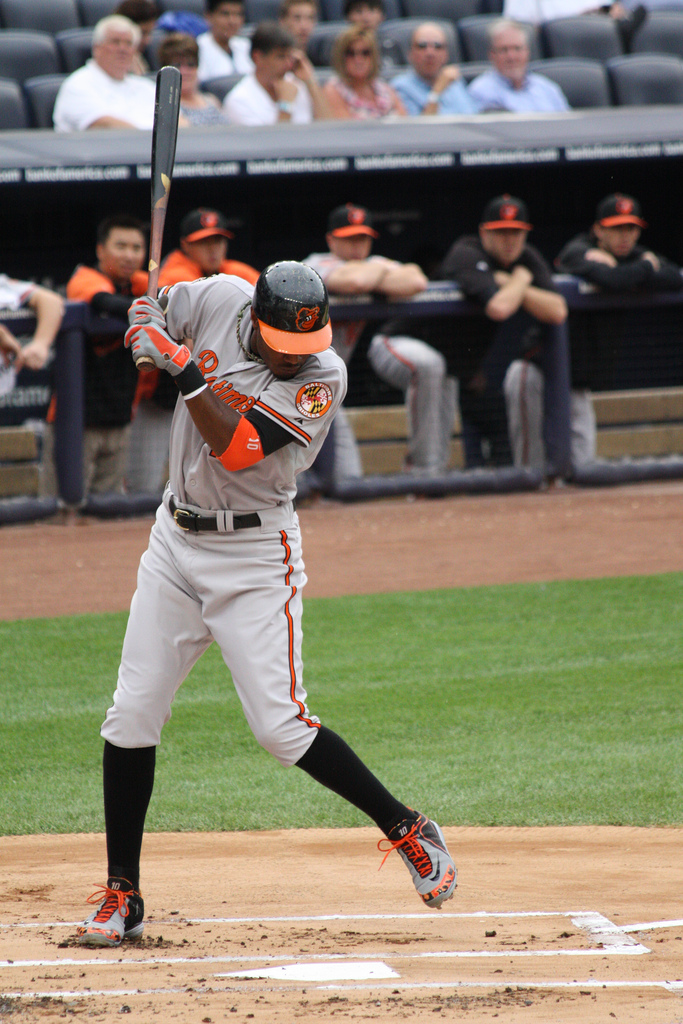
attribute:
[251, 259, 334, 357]
helmet — black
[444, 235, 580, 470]
uniform — black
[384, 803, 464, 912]
cleat — gray, black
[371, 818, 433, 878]
laces — orange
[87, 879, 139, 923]
laces — orange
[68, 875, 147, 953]
cleat — black, gray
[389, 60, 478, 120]
shirt — blue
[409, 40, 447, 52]
sunglasses — black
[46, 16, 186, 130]
man — old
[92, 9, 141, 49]
hair — white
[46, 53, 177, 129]
shirt — white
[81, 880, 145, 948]
shoe — black, gray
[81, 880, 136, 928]
shoelaces — orange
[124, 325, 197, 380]
glove — orange, gray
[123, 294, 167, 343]
glove — orange, gray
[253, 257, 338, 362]
helmet — shiny, black, orange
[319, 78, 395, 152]
woman — wearing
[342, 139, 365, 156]
sunglasses — black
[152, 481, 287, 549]
belt — black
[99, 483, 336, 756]
pants — white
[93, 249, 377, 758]
man — older, wearing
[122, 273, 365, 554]
shirt — white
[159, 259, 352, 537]
shirt — blue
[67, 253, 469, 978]
man — bald, wearing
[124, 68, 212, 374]
bat — metal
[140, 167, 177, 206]
star — gold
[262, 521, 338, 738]
stripe — black, orange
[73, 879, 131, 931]
shoelaces — orange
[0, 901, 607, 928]
line — white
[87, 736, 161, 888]
sock — black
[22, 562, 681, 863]
grass — green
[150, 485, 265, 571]
belt — black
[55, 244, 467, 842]
man — holding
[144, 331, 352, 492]
arm — folded